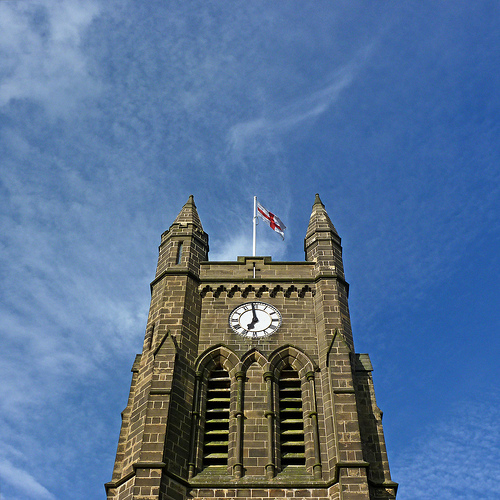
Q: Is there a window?
A: Yes, there is a window.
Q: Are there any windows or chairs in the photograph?
A: Yes, there is a window.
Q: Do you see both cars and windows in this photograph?
A: No, there is a window but no cars.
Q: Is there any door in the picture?
A: No, there are no doors.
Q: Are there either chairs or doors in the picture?
A: No, there are no doors or chairs.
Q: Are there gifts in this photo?
A: No, there are no gifts.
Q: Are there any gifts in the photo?
A: No, there are no gifts.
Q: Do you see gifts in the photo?
A: No, there are no gifts.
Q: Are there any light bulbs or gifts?
A: No, there are no gifts or light bulbs.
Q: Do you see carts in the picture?
A: No, there are no carts.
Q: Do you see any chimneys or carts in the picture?
A: No, there are no carts or chimneys.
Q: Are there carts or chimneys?
A: No, there are no carts or chimneys.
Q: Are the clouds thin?
A: Yes, the clouds are thin.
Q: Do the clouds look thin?
A: Yes, the clouds are thin.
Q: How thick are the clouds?
A: The clouds are thin.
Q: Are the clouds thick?
A: No, the clouds are thin.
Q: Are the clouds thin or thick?
A: The clouds are thin.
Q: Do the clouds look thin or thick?
A: The clouds are thin.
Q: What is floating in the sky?
A: The clouds are floating in the sky.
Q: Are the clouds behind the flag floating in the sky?
A: Yes, the clouds are floating in the sky.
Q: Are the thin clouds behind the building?
A: Yes, the clouds are behind the building.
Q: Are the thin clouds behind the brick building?
A: Yes, the clouds are behind the building.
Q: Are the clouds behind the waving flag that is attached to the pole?
A: Yes, the clouds are behind the flag.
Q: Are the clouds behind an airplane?
A: No, the clouds are behind the flag.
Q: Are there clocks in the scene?
A: Yes, there is a clock.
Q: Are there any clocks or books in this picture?
A: Yes, there is a clock.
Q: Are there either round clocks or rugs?
A: Yes, there is a round clock.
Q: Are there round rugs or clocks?
A: Yes, there is a round clock.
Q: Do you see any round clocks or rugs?
A: Yes, there is a round clock.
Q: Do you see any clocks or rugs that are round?
A: Yes, the clock is round.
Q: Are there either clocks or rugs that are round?
A: Yes, the clock is round.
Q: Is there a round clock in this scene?
A: Yes, there is a round clock.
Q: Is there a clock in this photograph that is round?
A: Yes, there is a clock that is round.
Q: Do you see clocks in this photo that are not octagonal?
A: Yes, there is an round clock.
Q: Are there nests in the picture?
A: No, there are no nests.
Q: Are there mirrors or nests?
A: No, there are no nests or mirrors.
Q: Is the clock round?
A: Yes, the clock is round.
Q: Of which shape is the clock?
A: The clock is round.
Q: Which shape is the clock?
A: The clock is round.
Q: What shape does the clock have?
A: The clock has round shape.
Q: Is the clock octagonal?
A: No, the clock is round.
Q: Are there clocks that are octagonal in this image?
A: No, there is a clock but it is round.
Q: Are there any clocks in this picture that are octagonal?
A: No, there is a clock but it is round.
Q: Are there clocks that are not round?
A: No, there is a clock but it is round.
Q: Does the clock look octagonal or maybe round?
A: The clock is round.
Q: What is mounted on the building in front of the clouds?
A: The clock is mounted on the building.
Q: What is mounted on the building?
A: The clock is mounted on the building.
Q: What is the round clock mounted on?
A: The clock is mounted on the building.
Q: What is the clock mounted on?
A: The clock is mounted on the building.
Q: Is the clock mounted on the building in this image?
A: Yes, the clock is mounted on the building.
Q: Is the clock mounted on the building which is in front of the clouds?
A: Yes, the clock is mounted on the building.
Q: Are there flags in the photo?
A: Yes, there is a flag.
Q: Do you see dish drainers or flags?
A: Yes, there is a flag.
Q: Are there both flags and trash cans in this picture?
A: No, there is a flag but no trash cans.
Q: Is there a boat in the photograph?
A: No, there are no boats.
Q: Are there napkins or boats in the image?
A: No, there are no boats or napkins.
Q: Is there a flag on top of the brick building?
A: Yes, there is a flag on top of the building.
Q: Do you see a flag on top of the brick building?
A: Yes, there is a flag on top of the building.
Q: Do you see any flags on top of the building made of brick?
A: Yes, there is a flag on top of the building.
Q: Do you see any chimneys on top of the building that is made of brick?
A: No, there is a flag on top of the building.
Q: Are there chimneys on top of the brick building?
A: No, there is a flag on top of the building.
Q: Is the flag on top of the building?
A: Yes, the flag is on top of the building.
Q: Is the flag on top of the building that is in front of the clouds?
A: Yes, the flag is on top of the building.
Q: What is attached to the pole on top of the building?
A: The flag is attached to the pole.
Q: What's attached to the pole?
A: The flag is attached to the pole.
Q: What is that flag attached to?
A: The flag is attached to the pole.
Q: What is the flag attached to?
A: The flag is attached to the pole.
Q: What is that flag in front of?
A: The flag is in front of the clouds.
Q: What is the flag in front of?
A: The flag is in front of the clouds.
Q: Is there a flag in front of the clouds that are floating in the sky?
A: Yes, there is a flag in front of the clouds.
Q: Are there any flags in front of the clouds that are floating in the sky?
A: Yes, there is a flag in front of the clouds.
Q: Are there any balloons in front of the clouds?
A: No, there is a flag in front of the clouds.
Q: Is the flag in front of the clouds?
A: Yes, the flag is in front of the clouds.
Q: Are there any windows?
A: Yes, there is a window.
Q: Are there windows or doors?
A: Yes, there is a window.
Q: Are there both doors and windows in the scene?
A: No, there is a window but no doors.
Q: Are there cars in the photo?
A: No, there are no cars.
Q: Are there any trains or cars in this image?
A: No, there are no cars or trains.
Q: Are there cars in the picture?
A: No, there are no cars.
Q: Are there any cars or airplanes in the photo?
A: No, there are no cars or airplanes.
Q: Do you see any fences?
A: No, there are no fences.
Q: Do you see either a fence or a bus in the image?
A: No, there are no fences or buses.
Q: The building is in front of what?
A: The building is in front of the clouds.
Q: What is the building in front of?
A: The building is in front of the clouds.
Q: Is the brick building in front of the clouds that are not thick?
A: Yes, the building is in front of the clouds.